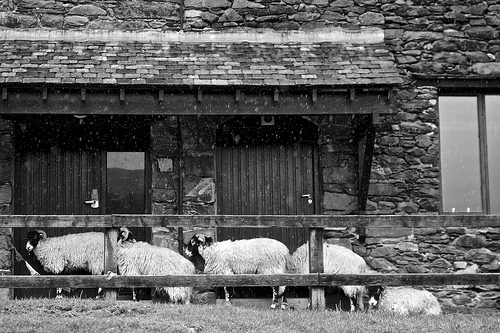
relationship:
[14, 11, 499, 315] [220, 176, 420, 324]
building behind sheep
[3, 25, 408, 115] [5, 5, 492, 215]
awning on side of building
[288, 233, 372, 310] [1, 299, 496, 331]
sheep standing on grass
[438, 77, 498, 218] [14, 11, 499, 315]
window on building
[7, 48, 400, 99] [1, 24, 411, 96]
shingles are on roof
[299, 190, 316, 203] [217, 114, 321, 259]
lock on door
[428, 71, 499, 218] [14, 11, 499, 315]
window on side of building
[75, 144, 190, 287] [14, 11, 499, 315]
door on building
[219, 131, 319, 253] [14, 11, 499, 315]
door on building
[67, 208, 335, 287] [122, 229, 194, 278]
fence near sheep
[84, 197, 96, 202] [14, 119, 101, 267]
handle on door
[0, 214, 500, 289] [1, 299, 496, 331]
fence on grass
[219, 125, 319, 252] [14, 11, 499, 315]
door on building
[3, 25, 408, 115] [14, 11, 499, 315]
awning on building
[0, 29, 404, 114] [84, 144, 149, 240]
roof over doorway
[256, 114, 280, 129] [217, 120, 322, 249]
object over door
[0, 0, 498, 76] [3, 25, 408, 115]
stone wall above awning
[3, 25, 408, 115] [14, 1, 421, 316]
awning attached to building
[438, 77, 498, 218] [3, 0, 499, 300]
window attached to building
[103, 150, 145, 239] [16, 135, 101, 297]
window next to door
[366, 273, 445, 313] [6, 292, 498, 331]
sheep lying on ground